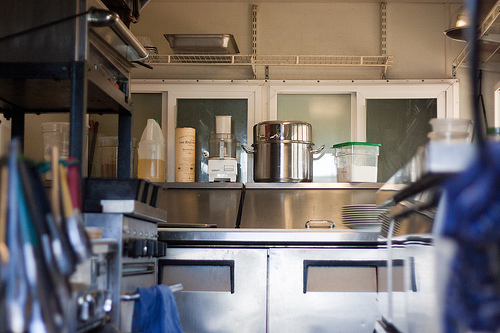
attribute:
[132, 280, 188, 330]
towel — blue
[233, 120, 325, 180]
pot — silver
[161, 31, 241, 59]
tray — silver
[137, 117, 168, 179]
bottle — plastic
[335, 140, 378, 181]
container — plastic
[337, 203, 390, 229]
plates — white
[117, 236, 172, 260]
knobs — black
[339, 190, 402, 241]
dishes — white, stacked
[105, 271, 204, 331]
towel — blue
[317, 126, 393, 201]
container — green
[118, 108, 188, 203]
bottle — plastic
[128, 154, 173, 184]
substance — liquid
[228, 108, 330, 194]
pot — large, metal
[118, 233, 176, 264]
knobs — black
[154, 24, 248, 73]
tray — metal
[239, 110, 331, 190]
pot — shiny, covered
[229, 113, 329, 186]
pot — shiny, metal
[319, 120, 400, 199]
container — plastic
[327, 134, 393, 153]
lid — green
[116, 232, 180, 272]
oven knobs — black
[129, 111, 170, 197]
container — half empty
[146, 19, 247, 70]
pan — shiny, rectangular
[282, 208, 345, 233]
handle — shiny, metal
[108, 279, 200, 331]
dishcloth — blue